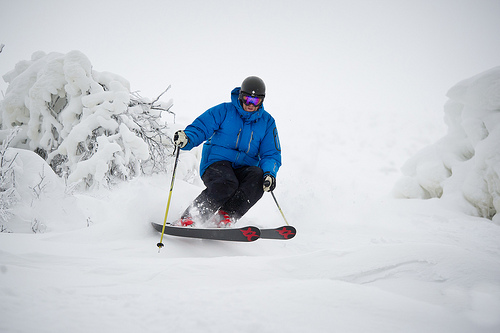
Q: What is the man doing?
A: Skiing.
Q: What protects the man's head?
A: Helmet.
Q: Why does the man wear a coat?
A: Cold weather.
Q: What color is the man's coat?
A: Blue.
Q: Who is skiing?
A: A man.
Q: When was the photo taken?
A: Daytime.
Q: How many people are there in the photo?
A: One.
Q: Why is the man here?
A: Skiing.